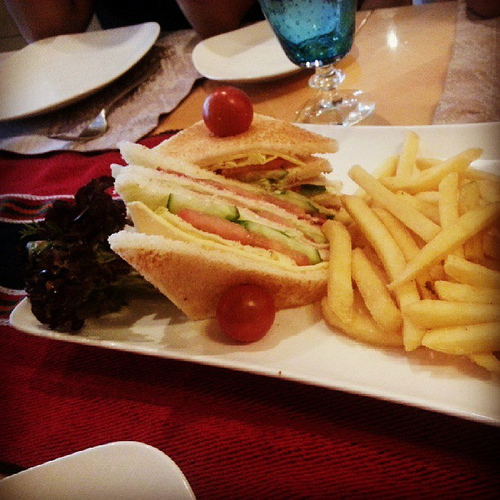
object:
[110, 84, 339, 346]
sandwich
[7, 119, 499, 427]
plate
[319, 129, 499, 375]
french fries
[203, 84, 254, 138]
cherry tomato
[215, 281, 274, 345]
cherry tomato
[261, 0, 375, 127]
glass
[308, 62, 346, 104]
stem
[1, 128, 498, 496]
runner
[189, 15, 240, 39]
elbow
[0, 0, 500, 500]
table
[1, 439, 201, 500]
plate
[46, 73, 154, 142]
fork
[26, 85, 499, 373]
food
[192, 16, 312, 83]
plate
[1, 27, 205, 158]
placemat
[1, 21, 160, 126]
plate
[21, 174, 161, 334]
garnish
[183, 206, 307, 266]
tomato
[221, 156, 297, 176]
tomato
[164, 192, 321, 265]
cucumber slices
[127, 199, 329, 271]
cheese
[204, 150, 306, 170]
cheese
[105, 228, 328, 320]
bread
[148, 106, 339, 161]
bread